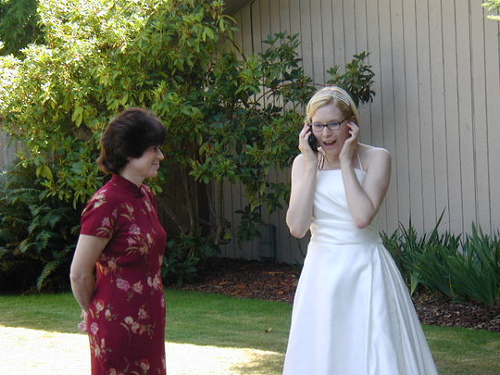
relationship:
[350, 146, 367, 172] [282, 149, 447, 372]
strap on dress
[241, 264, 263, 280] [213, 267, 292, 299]
leaves on ground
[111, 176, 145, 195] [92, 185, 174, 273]
collar on dress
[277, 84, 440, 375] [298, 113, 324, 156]
girl on phone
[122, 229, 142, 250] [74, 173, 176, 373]
flowers on dress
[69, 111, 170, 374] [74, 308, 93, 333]
mother has hands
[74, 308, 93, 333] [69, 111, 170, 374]
hands behind mother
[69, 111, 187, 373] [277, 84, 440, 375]
mother watching girl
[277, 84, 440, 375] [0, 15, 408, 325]
girl in yard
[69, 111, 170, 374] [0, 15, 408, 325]
mother in yard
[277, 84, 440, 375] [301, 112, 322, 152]
girl on phone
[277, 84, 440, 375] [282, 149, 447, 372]
girl in dress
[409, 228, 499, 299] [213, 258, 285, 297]
garden covered with mulch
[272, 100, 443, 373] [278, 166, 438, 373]
girl in dress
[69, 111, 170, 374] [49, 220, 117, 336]
mother with arms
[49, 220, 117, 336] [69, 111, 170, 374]
arms behind mother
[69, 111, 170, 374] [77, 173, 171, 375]
mother wearing dress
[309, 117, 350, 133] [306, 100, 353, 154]
eyeglasses on girl`s face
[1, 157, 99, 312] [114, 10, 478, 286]
bushes by house